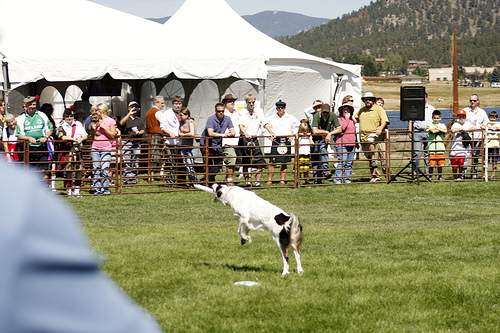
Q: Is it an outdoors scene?
A: Yes, it is outdoors.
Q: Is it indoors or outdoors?
A: It is outdoors.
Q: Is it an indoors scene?
A: No, it is outdoors.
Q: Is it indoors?
A: No, it is outdoors.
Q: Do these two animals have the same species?
A: No, they are goats and dogs.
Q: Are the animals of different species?
A: Yes, they are goats and dogs.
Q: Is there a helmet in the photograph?
A: No, there are no helmets.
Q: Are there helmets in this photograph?
A: No, there are no helmets.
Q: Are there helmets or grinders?
A: No, there are no helmets or grinders.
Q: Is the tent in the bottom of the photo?
A: No, the tent is in the top of the image.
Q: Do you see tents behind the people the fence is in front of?
A: Yes, there is a tent behind the people.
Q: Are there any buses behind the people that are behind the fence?
A: No, there is a tent behind the people.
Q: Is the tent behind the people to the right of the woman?
A: Yes, the tent is behind the people.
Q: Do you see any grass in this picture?
A: Yes, there is grass.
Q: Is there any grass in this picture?
A: Yes, there is grass.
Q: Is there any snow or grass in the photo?
A: Yes, there is grass.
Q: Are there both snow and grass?
A: No, there is grass but no snow.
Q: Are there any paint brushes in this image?
A: No, there are no paint brushes.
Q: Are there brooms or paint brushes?
A: No, there are no paint brushes or brooms.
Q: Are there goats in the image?
A: Yes, there is a goat.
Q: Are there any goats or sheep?
A: Yes, there is a goat.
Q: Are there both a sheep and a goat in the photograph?
A: No, there is a goat but no sheep.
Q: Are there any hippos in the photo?
A: No, there are no hippos.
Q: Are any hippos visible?
A: No, there are no hippos.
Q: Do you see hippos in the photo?
A: No, there are no hippos.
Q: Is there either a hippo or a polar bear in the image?
A: No, there are no hippos or polar bears.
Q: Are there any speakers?
A: Yes, there is a speaker.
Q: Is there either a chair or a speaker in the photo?
A: Yes, there is a speaker.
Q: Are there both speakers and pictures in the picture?
A: No, there is a speaker but no pictures.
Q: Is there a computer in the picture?
A: No, there are no computers.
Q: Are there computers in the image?
A: No, there are no computers.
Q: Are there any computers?
A: No, there are no computers.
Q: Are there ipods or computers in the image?
A: No, there are no computers or ipods.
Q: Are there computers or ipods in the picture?
A: No, there are no computers or ipods.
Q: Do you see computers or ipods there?
A: No, there are no computers or ipods.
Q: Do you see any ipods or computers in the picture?
A: No, there are no computers or ipods.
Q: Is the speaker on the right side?
A: Yes, the speaker is on the right of the image.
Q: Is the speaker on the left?
A: No, the speaker is on the right of the image.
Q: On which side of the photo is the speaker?
A: The speaker is on the right of the image.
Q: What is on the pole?
A: The speaker is on the pole.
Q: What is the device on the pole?
A: The device is a speaker.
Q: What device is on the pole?
A: The device is a speaker.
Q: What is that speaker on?
A: The speaker is on the pole.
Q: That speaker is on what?
A: The speaker is on the pole.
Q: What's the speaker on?
A: The speaker is on the pole.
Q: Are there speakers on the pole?
A: Yes, there is a speaker on the pole.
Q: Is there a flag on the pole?
A: No, there is a speaker on the pole.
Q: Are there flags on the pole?
A: No, there is a speaker on the pole.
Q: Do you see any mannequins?
A: No, there are no mannequins.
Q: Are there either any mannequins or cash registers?
A: No, there are no mannequins or cash registers.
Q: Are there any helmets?
A: No, there are no helmets.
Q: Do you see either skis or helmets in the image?
A: No, there are no helmets or skis.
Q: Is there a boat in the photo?
A: No, there are no boats.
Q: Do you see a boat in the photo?
A: No, there are no boats.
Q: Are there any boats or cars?
A: No, there are no boats or cars.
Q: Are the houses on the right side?
A: Yes, the houses are on the right of the image.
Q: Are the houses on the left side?
A: No, the houses are on the right of the image.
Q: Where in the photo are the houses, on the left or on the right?
A: The houses are on the right of the image.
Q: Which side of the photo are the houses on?
A: The houses are on the right of the image.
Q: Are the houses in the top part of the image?
A: Yes, the houses are in the top of the image.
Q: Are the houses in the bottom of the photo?
A: No, the houses are in the top of the image.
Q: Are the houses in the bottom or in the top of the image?
A: The houses are in the top of the image.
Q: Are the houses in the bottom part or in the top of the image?
A: The houses are in the top of the image.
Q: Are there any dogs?
A: Yes, there is a dog.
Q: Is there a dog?
A: Yes, there is a dog.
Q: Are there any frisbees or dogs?
A: Yes, there is a dog.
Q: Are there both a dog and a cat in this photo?
A: No, there is a dog but no cats.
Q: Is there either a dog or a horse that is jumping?
A: Yes, the dog is jumping.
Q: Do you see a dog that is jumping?
A: Yes, there is a dog that is jumping.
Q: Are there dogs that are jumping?
A: Yes, there is a dog that is jumping.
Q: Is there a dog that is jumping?
A: Yes, there is a dog that is jumping.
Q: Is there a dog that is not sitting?
A: Yes, there is a dog that is jumping.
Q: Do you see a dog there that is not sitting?
A: Yes, there is a dog that is jumping .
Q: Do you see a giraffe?
A: No, there are no giraffes.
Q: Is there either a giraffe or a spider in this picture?
A: No, there are no giraffes or spiders.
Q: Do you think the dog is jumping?
A: Yes, the dog is jumping.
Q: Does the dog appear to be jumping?
A: Yes, the dog is jumping.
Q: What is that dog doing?
A: The dog is jumping.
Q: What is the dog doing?
A: The dog is jumping.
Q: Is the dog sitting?
A: No, the dog is jumping.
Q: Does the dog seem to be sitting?
A: No, the dog is jumping.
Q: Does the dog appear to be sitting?
A: No, the dog is jumping.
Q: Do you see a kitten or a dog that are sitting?
A: No, there is a dog but it is jumping.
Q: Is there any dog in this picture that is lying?
A: No, there is a dog but it is jumping.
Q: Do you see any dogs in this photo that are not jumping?
A: No, there is a dog but it is jumping.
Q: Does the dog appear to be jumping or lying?
A: The dog is jumping.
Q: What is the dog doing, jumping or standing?
A: The dog is jumping.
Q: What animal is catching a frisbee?
A: The dog is catching a frisbee.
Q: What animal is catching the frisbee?
A: The dog is catching a frisbee.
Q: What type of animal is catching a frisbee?
A: The animal is a dog.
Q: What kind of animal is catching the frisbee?
A: The animal is a dog.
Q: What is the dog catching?
A: The dog is catching a frisbee.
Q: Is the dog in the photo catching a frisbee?
A: Yes, the dog is catching a frisbee.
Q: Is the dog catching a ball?
A: No, the dog is catching a frisbee.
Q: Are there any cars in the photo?
A: No, there are no cars.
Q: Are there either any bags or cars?
A: No, there are no cars or bags.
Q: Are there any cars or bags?
A: No, there are no cars or bags.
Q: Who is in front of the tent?
A: The people are in front of the tent.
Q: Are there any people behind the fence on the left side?
A: Yes, there are people behind the fence.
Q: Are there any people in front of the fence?
A: No, the people are behind the fence.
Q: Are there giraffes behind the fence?
A: No, there are people behind the fence.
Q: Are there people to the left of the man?
A: Yes, there are people to the left of the man.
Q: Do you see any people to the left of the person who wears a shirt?
A: Yes, there are people to the left of the man.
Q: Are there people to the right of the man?
A: No, the people are to the left of the man.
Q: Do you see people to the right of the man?
A: No, the people are to the left of the man.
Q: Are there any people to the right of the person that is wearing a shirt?
A: No, the people are to the left of the man.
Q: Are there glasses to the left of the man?
A: No, there are people to the left of the man.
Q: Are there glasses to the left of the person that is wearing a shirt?
A: No, there are people to the left of the man.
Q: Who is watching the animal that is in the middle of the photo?
A: The people are watching the goat.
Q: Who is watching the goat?
A: The people are watching the goat.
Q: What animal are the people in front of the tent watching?
A: The people are watching the goat.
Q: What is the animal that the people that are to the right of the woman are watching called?
A: The animal is a goat.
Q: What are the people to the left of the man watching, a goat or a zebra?
A: The people are watching a goat.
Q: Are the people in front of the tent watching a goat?
A: Yes, the people are watching a goat.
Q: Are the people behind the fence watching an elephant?
A: No, the people are watching a goat.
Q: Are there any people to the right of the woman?
A: Yes, there are people to the right of the woman.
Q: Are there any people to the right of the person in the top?
A: Yes, there are people to the right of the woman.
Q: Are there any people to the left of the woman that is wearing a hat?
A: No, the people are to the right of the woman.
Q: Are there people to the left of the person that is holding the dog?
A: No, the people are to the right of the woman.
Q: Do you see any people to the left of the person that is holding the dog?
A: No, the people are to the right of the woman.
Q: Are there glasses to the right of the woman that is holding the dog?
A: No, there are people to the right of the woman.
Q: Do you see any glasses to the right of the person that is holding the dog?
A: No, there are people to the right of the woman.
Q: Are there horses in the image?
A: No, there are no horses.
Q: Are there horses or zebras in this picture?
A: No, there are no horses or zebras.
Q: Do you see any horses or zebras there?
A: No, there are no horses or zebras.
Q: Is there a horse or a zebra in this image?
A: No, there are no horses or zebras.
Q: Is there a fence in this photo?
A: Yes, there is a fence.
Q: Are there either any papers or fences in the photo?
A: Yes, there is a fence.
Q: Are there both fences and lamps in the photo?
A: No, there is a fence but no lamps.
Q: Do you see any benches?
A: No, there are no benches.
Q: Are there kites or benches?
A: No, there are no benches or kites.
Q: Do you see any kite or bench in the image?
A: No, there are no benches or kites.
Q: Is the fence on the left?
A: Yes, the fence is on the left of the image.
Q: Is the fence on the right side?
A: No, the fence is on the left of the image.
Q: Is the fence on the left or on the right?
A: The fence is on the left of the image.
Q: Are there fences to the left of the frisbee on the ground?
A: Yes, there is a fence to the left of the frisbee.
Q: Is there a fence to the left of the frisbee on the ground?
A: Yes, there is a fence to the left of the frisbee.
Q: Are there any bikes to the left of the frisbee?
A: No, there is a fence to the left of the frisbee.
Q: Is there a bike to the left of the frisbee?
A: No, there is a fence to the left of the frisbee.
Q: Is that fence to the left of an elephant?
A: No, the fence is to the left of the frisbee.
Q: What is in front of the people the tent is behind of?
A: The fence is in front of the people.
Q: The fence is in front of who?
A: The fence is in front of the people.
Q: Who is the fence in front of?
A: The fence is in front of the people.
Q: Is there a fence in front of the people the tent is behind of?
A: Yes, there is a fence in front of the people.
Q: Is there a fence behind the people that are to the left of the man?
A: No, the fence is in front of the people.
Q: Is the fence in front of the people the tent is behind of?
A: Yes, the fence is in front of the people.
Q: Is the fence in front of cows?
A: No, the fence is in front of the people.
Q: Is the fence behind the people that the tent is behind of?
A: No, the fence is in front of the people.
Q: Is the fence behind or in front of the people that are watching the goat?
A: The fence is in front of the people.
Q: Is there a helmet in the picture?
A: No, there are no helmets.